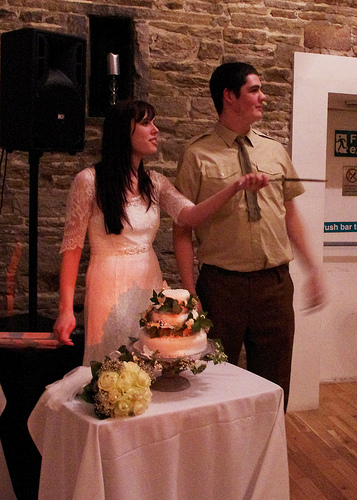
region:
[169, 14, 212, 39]
the wall is brown in colour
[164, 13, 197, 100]
the wall is bricked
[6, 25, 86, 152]
the speaker box is black in colour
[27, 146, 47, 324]
the pole is black in colour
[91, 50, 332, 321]
a man and a woman are standing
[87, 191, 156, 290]
the woman has a white lace dress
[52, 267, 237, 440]
the cake is on the table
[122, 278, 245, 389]
the cake is decorated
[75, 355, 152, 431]
a bouquet of flower is on the table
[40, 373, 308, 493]
the table is covered by a white clothe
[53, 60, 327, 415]
A man and woman standing by a wedding cake.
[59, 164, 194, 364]
The woman is wearing a white lace dress.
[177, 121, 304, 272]
The man is wearing a tan shirt.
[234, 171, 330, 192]
The woman is holding a knife in her hand.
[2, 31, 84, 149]
A black speaker next to the woman.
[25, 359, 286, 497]
White tablecloth on the table.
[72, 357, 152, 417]
Wedding bouquet on top of the table.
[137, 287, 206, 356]
A white floral wedding cake.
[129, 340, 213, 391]
A glass cake plate.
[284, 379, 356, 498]
Brown hardwood flooring on the floor.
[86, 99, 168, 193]
the head of a woman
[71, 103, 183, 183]
the face of a woman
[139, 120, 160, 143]
the nose of a woman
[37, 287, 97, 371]
the hand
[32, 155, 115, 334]
the arm of a woman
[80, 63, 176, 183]
the hair of a woman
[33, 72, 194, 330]
a woman wearing a dress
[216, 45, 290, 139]
the head of a man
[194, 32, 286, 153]
the face of a man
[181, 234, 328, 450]
the legs of a a man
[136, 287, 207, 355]
the 3 tiered cake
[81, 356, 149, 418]
the bouquet of flowers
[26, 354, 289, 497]
the white table cloth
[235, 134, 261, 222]
the tie around the man's neck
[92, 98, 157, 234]
the hair on the woman's head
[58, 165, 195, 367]
the wedding dress on the woman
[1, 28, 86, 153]
the large speaker near the woman's head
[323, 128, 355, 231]
the signs on the door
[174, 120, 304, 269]
the short sleeved shirt on the man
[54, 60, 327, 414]
the man and woman standing in front of the cake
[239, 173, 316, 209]
bride is holding a knife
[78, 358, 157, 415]
yellow buquet on the table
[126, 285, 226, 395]
wedding cake on the table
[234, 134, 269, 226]
man is wearing a short tie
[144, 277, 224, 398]
cake has flowers on it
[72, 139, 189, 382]
bride is wearing a wedding dress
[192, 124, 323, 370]
man is wearing a brown shirt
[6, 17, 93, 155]
speaker beside the bride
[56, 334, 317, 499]
tablecloth on the table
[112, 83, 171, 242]
bride has long dark hair